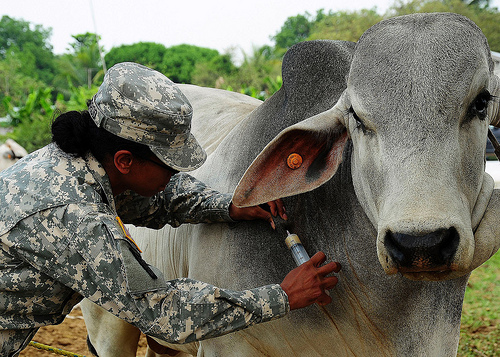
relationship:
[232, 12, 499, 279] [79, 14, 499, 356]
head of cow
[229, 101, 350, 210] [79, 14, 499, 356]
ear of cow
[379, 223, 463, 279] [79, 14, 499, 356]
nose of cow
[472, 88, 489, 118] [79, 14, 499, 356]
eye of cow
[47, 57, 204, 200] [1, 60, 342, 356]
head of woman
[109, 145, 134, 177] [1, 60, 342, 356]
ear of woman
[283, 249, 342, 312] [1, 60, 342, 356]
hand of woman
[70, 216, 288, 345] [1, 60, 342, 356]
arm of woman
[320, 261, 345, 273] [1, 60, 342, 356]
finger of woman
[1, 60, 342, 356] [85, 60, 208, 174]
woman wearing hat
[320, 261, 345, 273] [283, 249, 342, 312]
finger of hand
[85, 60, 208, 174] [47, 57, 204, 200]
hat on head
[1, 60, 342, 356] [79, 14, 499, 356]
woman next to cow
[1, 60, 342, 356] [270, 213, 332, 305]
woman holding needle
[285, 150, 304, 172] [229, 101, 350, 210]
stud in ear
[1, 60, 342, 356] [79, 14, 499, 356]
woman injecting cow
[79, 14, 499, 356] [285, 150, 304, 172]
cow with a stud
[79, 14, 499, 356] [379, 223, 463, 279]
cow with nose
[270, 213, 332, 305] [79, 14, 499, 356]
needle in cow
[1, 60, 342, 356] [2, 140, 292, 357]
woman wearing jacket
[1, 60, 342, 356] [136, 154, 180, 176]
woman wearing glasses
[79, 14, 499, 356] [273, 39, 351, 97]
cow with hump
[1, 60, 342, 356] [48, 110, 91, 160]
woman with ponytail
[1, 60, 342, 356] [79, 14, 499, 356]
woman giving shot to cow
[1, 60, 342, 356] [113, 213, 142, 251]
woman wearing badge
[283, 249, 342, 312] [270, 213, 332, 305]
hand holding needle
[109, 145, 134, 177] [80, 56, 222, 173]
ear under hat